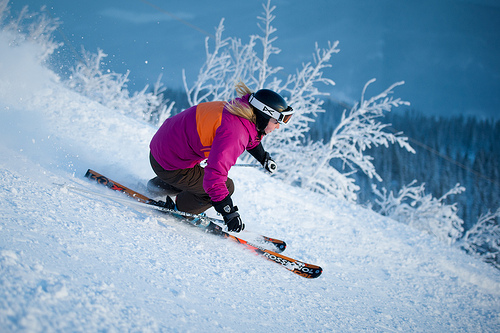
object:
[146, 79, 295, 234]
woman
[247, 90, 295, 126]
white goggles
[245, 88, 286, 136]
head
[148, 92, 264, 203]
jacket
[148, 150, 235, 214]
pants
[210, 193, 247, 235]
glove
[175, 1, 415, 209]
tree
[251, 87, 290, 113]
helmet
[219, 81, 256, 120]
hair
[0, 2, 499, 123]
sky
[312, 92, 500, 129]
tree line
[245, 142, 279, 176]
glove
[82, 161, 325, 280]
ski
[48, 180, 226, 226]
ski pole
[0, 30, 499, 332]
mountain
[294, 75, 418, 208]
tree limb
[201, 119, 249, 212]
arm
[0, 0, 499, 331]
snow